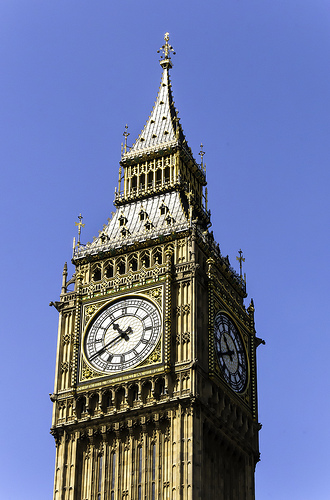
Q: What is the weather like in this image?
A: It is cloudless.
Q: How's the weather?
A: It is cloudless.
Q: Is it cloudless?
A: Yes, it is cloudless.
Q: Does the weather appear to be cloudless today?
A: Yes, it is cloudless.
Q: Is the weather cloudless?
A: Yes, it is cloudless.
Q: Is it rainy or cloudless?
A: It is cloudless.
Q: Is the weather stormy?
A: No, it is cloudless.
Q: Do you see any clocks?
A: Yes, there is a clock.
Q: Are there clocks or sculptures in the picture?
A: Yes, there is a clock.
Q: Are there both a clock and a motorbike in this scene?
A: No, there is a clock but no motorcycles.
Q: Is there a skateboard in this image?
A: No, there are no skateboards.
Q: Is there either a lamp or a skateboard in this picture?
A: No, there are no skateboards or lamps.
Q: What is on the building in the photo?
A: The clock is on the building.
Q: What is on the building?
A: The clock is on the building.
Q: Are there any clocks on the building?
A: Yes, there is a clock on the building.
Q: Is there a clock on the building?
A: Yes, there is a clock on the building.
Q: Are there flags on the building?
A: No, there is a clock on the building.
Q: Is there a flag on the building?
A: No, there is a clock on the building.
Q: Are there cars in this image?
A: No, there are no cars.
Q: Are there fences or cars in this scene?
A: No, there are no cars or fences.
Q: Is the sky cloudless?
A: Yes, the sky is cloudless.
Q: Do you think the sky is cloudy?
A: No, the sky is cloudless.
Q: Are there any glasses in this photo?
A: No, there are no glasses.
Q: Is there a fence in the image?
A: No, there are no fences.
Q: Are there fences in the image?
A: No, there are no fences.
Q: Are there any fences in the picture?
A: No, there are no fences.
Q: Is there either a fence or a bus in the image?
A: No, there are no fences or buses.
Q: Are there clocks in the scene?
A: Yes, there is a clock.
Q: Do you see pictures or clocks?
A: Yes, there is a clock.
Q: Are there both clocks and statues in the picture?
A: No, there is a clock but no statues.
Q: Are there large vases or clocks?
A: Yes, there is a large clock.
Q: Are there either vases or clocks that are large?
A: Yes, the clock is large.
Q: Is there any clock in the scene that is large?
A: Yes, there is a large clock.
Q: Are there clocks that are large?
A: Yes, there is a clock that is large.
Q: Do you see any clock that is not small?
A: Yes, there is a large clock.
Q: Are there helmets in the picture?
A: No, there are no helmets.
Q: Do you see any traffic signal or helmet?
A: No, there are no helmets or traffic lights.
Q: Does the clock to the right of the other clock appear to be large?
A: Yes, the clock is large.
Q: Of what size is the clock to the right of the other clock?
A: The clock is large.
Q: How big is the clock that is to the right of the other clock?
A: The clock is large.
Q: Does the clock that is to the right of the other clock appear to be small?
A: No, the clock is large.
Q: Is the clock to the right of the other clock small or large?
A: The clock is large.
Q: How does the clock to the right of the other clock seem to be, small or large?
A: The clock is large.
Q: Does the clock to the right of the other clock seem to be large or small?
A: The clock is large.